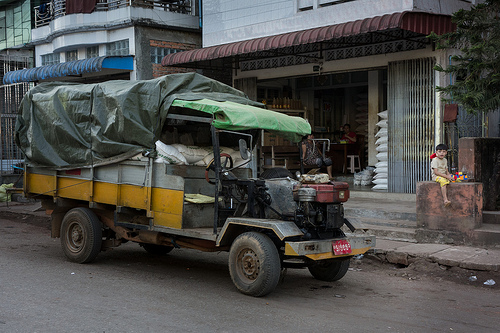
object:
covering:
[3, 55, 134, 85]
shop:
[31, 55, 136, 87]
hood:
[231, 173, 363, 243]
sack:
[154, 140, 188, 165]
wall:
[202, 0, 412, 43]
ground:
[0, 220, 500, 333]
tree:
[421, 1, 499, 121]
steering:
[205, 152, 235, 185]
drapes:
[25, 60, 313, 169]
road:
[3, 226, 497, 331]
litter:
[483, 278, 497, 286]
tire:
[227, 231, 282, 297]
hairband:
[430, 153, 436, 159]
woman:
[339, 124, 356, 174]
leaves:
[452, 2, 500, 33]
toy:
[449, 171, 468, 181]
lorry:
[14, 72, 377, 297]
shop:
[232, 44, 499, 194]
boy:
[431, 143, 465, 207]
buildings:
[24, 2, 201, 77]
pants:
[434, 175, 450, 187]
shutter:
[403, 73, 438, 155]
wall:
[416, 182, 475, 237]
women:
[300, 131, 335, 182]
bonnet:
[386, 59, 459, 194]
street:
[5, 243, 480, 331]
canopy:
[13, 72, 310, 172]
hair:
[436, 144, 448, 152]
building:
[160, 0, 470, 195]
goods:
[144, 140, 248, 169]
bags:
[354, 168, 373, 186]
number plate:
[332, 240, 352, 255]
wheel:
[58, 207, 102, 264]